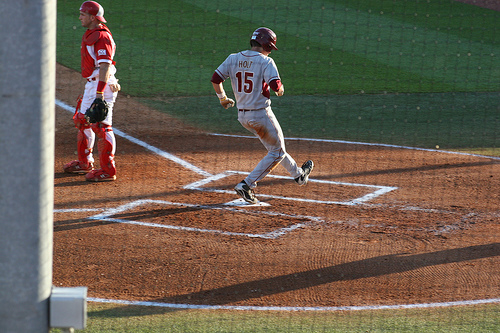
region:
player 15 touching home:
[196, 17, 343, 221]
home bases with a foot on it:
[220, 185, 266, 217]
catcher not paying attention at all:
[68, 0, 150, 203]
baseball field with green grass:
[114, 1, 498, 139]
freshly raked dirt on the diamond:
[69, 205, 487, 304]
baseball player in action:
[185, 14, 354, 244]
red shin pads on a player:
[68, 109, 119, 179]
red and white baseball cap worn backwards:
[75, 0, 113, 22]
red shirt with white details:
[76, 17, 116, 74]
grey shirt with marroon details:
[208, 45, 288, 110]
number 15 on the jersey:
[233, 69, 257, 96]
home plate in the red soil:
[225, 189, 275, 207]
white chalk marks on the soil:
[90, 124, 398, 256]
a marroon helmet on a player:
[250, 24, 281, 54]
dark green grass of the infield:
[51, 0, 492, 143]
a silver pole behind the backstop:
[2, 3, 56, 331]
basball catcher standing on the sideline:
[65, 2, 122, 182]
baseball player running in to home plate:
[205, 26, 315, 206]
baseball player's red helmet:
[250, 24, 282, 54]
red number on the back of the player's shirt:
[233, 69, 255, 96]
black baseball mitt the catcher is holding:
[84, 96, 109, 123]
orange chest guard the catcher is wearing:
[79, 26, 113, 79]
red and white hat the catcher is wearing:
[79, 2, 106, 19]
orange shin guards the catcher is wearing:
[72, 116, 112, 170]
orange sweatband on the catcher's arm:
[95, 75, 108, 94]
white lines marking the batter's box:
[82, 195, 323, 245]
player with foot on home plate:
[203, 20, 321, 215]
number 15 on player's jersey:
[230, 67, 259, 98]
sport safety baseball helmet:
[246, 25, 282, 55]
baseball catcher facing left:
[65, 2, 123, 187]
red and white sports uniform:
[63, 27, 120, 184]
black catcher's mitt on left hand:
[81, 95, 112, 128]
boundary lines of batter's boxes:
[84, 161, 401, 247]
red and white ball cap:
[75, 1, 111, 25]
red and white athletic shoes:
[62, 158, 119, 187]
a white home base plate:
[225, 194, 270, 209]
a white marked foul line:
[55, 94, 211, 175]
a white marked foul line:
[53, 203, 105, 213]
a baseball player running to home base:
[211, 26, 316, 208]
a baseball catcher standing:
[62, 3, 118, 181]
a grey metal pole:
[0, 1, 56, 332]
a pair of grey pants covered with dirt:
[234, 108, 301, 188]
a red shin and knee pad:
[73, 111, 89, 163]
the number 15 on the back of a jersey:
[236, 70, 253, 90]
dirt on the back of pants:
[246, 121, 282, 147]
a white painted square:
[92, 198, 320, 241]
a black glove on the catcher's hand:
[85, 98, 109, 124]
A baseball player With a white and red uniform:
[215, 32, 302, 209]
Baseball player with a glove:
[77, 53, 129, 146]